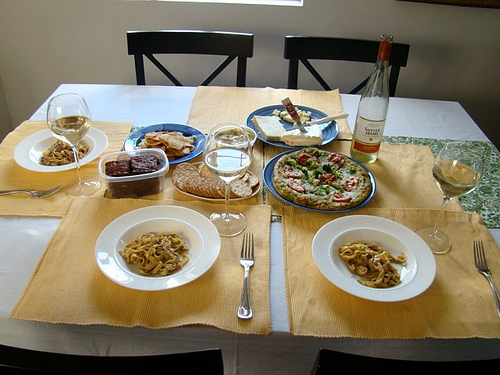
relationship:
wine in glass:
[53, 113, 91, 150] [46, 90, 101, 198]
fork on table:
[237, 231, 256, 323] [0, 82, 499, 373]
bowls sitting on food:
[93, 204, 437, 303] [118, 232, 189, 275]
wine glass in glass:
[46, 93, 102, 196] [427, 136, 484, 254]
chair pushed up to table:
[283, 36, 411, 97] [0, 82, 499, 373]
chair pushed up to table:
[125, 31, 253, 88] [0, 82, 499, 373]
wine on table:
[344, 37, 424, 174] [356, 137, 463, 258]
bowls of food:
[93, 204, 437, 303] [120, 227, 188, 274]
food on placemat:
[120, 227, 188, 274] [7, 190, 278, 334]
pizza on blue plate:
[268, 149, 375, 217] [262, 148, 379, 213]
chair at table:
[124, 27, 254, 86] [0, 82, 499, 373]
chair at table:
[282, 32, 410, 94] [0, 82, 499, 373]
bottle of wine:
[347, 33, 390, 167] [305, 136, 394, 188]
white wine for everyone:
[350, 32, 394, 164] [152, 169, 435, 294]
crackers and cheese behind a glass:
[169, 157, 259, 201] [206, 134, 489, 233]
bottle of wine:
[347, 33, 390, 167] [349, 141, 380, 163]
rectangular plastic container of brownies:
[75, 147, 167, 227] [99, 144, 171, 199]